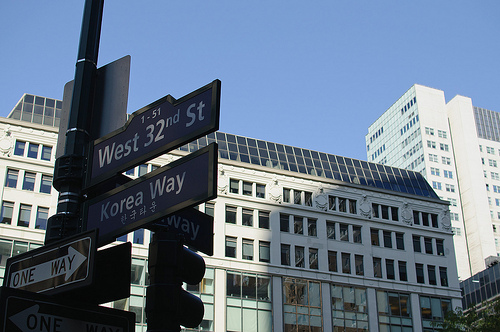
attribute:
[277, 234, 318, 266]
window — Closed 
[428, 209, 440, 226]
window — glass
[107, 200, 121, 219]
letter — white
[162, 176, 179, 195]
letter — white